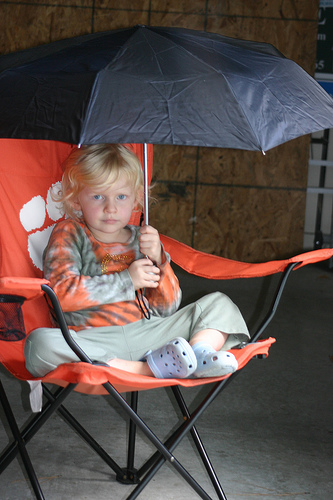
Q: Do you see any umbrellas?
A: Yes, there is an umbrella.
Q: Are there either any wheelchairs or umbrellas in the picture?
A: Yes, there is an umbrella.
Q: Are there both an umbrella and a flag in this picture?
A: No, there is an umbrella but no flags.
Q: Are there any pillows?
A: No, there are no pillows.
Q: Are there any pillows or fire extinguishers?
A: No, there are no pillows or fire extinguishers.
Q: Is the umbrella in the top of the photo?
A: Yes, the umbrella is in the top of the image.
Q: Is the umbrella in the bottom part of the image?
A: No, the umbrella is in the top of the image.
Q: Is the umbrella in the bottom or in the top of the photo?
A: The umbrella is in the top of the image.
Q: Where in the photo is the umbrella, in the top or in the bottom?
A: The umbrella is in the top of the image.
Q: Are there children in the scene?
A: Yes, there is a child.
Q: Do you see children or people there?
A: Yes, there is a child.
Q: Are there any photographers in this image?
A: No, there are no photographers.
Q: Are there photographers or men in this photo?
A: No, there are no photographers or men.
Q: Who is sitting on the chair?
A: The kid is sitting on the chair.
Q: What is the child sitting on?
A: The child is sitting on the chair.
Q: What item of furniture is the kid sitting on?
A: The kid is sitting on the chair.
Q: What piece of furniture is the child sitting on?
A: The kid is sitting on the chair.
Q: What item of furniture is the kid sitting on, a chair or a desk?
A: The kid is sitting on a chair.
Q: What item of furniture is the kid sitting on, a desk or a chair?
A: The kid is sitting on a chair.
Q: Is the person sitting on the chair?
A: Yes, the child is sitting on the chair.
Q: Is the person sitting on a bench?
A: No, the child is sitting on the chair.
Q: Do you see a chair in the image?
A: Yes, there is a chair.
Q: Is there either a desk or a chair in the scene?
A: Yes, there is a chair.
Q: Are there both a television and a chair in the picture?
A: No, there is a chair but no televisions.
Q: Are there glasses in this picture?
A: No, there are no glasses.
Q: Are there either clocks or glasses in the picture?
A: No, there are no glasses or clocks.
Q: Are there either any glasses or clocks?
A: No, there are no glasses or clocks.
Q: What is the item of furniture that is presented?
A: The piece of furniture is a chair.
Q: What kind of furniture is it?
A: The piece of furniture is a chair.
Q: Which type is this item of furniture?
A: This is a chair.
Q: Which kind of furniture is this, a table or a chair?
A: This is a chair.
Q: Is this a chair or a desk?
A: This is a chair.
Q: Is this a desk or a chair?
A: This is a chair.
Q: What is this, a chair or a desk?
A: This is a chair.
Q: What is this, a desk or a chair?
A: This is a chair.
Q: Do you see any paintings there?
A: No, there are no paintings.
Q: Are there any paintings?
A: No, there are no paintings.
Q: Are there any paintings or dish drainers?
A: No, there are no paintings or dish drainers.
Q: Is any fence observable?
A: No, there are no fences.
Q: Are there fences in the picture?
A: No, there are no fences.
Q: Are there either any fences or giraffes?
A: No, there are no fences or giraffes.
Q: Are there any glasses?
A: No, there are no glasses.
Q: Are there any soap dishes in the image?
A: No, there are no soap dishes.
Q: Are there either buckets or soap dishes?
A: No, there are no soap dishes or buckets.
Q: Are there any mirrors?
A: No, there are no mirrors.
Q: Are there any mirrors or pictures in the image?
A: No, there are no mirrors or pictures.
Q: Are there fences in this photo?
A: No, there are no fences.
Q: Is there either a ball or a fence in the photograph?
A: No, there are no fences or balls.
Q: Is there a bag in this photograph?
A: No, there are no bags.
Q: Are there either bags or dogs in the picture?
A: No, there are no bags or dogs.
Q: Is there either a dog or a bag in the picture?
A: No, there are no bags or dogs.